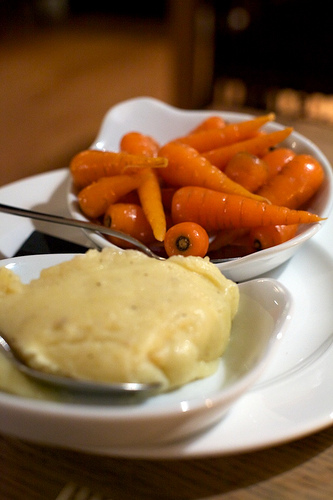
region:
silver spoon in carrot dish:
[15, 195, 246, 285]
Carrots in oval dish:
[108, 127, 264, 211]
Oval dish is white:
[126, 91, 331, 268]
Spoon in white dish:
[35, 357, 147, 430]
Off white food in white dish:
[63, 250, 293, 377]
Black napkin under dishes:
[33, 134, 66, 294]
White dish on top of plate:
[15, 240, 266, 450]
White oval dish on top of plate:
[81, 90, 329, 281]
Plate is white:
[298, 366, 322, 434]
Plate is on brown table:
[23, 454, 238, 482]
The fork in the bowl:
[0, 196, 243, 266]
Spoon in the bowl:
[0, 330, 165, 396]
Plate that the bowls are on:
[1, 162, 331, 460]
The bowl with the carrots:
[64, 96, 331, 282]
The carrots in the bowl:
[69, 112, 327, 256]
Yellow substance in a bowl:
[0, 249, 241, 396]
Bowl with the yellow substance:
[0, 246, 296, 442]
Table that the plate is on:
[0, 111, 332, 499]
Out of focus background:
[0, 0, 329, 178]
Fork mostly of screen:
[52, 479, 114, 498]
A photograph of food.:
[0, 1, 331, 499]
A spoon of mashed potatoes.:
[0, 247, 239, 401]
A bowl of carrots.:
[66, 97, 326, 275]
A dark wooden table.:
[0, 456, 328, 498]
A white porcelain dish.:
[277, 325, 329, 436]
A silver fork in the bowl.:
[0, 193, 249, 264]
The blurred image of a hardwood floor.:
[1, 7, 175, 85]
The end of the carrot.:
[170, 232, 187, 251]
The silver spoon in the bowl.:
[23, 361, 148, 390]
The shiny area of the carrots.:
[126, 208, 139, 219]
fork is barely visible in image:
[45, 477, 96, 498]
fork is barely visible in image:
[46, 469, 118, 498]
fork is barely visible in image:
[55, 483, 72, 494]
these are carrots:
[92, 117, 309, 242]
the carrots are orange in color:
[112, 131, 278, 217]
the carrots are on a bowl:
[84, 86, 322, 254]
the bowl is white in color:
[80, 93, 329, 260]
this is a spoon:
[1, 193, 161, 259]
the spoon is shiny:
[0, 194, 157, 255]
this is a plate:
[0, 60, 332, 485]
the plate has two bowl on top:
[0, 93, 332, 459]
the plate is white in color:
[254, 214, 332, 449]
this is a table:
[0, 443, 332, 496]